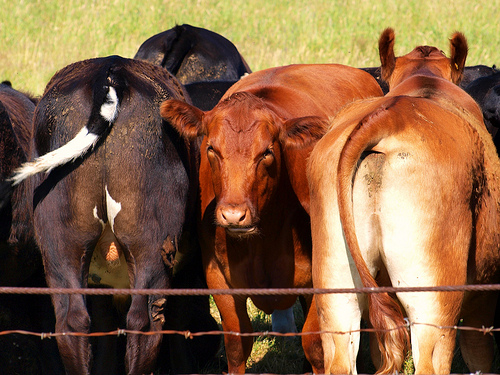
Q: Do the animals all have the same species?
A: Yes, all the animals are cows.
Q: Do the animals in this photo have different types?
A: No, all the animals are cows.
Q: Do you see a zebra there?
A: No, there are no zebras.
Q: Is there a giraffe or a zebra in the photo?
A: No, there are no zebras or giraffes.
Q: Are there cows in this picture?
A: Yes, there is a cow.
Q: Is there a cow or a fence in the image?
A: Yes, there is a cow.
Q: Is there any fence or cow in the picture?
A: Yes, there is a cow.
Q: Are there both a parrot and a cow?
A: No, there is a cow but no parrots.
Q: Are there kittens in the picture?
A: No, there are no kittens.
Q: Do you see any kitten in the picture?
A: No, there are no kittens.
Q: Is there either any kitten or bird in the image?
A: No, there are no kittens or birds.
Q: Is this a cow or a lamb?
A: This is a cow.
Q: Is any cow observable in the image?
A: Yes, there is a cow.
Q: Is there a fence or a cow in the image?
A: Yes, there is a cow.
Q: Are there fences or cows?
A: Yes, there is a cow.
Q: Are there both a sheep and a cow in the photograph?
A: No, there is a cow but no sheep.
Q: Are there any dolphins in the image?
A: No, there are no dolphins.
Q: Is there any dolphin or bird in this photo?
A: No, there are no dolphins or birds.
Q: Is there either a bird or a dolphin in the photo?
A: No, there are no dolphins or birds.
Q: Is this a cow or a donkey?
A: This is a cow.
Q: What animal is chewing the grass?
A: The animal is a cow.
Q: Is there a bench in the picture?
A: No, there are no benches.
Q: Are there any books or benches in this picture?
A: No, there are no benches or books.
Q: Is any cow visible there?
A: Yes, there is a cow.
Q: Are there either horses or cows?
A: Yes, there is a cow.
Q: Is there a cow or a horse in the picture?
A: Yes, there is a cow.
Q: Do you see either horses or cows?
A: Yes, there is a cow.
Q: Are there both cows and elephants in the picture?
A: No, there is a cow but no elephants.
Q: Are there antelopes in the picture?
A: No, there are no antelopes.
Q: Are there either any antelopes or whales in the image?
A: No, there are no antelopes or whales.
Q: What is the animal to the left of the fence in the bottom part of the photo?
A: The animal is a cow.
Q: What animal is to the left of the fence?
A: The animal is a cow.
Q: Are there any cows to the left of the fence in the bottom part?
A: Yes, there is a cow to the left of the fence.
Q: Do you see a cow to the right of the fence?
A: No, the cow is to the left of the fence.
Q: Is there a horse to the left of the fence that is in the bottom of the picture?
A: No, there is a cow to the left of the fence.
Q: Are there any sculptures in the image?
A: No, there are no sculptures.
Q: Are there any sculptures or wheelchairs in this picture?
A: No, there are no sculptures or wheelchairs.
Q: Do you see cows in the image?
A: Yes, there is a cow.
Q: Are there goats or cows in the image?
A: Yes, there is a cow.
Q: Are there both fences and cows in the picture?
A: Yes, there are both a cow and a fence.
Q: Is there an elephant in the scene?
A: No, there are no elephants.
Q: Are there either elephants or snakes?
A: No, there are no elephants or snakes.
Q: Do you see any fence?
A: Yes, there is a fence.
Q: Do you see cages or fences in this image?
A: Yes, there is a fence.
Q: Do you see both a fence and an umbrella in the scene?
A: No, there is a fence but no umbrellas.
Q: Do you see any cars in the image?
A: No, there are no cars.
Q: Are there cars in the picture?
A: No, there are no cars.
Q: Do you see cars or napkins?
A: No, there are no cars or napkins.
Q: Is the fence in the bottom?
A: Yes, the fence is in the bottom of the image.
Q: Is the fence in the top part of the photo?
A: No, the fence is in the bottom of the image.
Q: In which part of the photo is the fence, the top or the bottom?
A: The fence is in the bottom of the image.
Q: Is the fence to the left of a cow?
A: No, the fence is to the right of a cow.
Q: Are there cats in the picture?
A: No, there are no cats.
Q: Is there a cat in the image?
A: No, there are no cats.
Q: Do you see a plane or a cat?
A: No, there are no cats or airplanes.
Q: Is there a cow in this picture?
A: Yes, there are cows.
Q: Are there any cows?
A: Yes, there are cows.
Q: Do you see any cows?
A: Yes, there are cows.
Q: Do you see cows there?
A: Yes, there are cows.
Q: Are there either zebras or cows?
A: Yes, there are cows.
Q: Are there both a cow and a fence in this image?
A: Yes, there are both a cow and a fence.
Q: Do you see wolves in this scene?
A: No, there are no wolves.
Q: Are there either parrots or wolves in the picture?
A: No, there are no wolves or parrots.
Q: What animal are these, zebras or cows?
A: These are cows.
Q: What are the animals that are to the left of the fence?
A: The animals are cows.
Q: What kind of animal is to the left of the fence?
A: The animals are cows.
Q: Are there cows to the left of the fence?
A: Yes, there are cows to the left of the fence.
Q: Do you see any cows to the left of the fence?
A: Yes, there are cows to the left of the fence.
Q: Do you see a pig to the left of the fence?
A: No, there are cows to the left of the fence.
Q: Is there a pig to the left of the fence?
A: No, there are cows to the left of the fence.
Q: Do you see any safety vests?
A: No, there are no safety vests.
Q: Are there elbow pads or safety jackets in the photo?
A: No, there are no safety jackets or elbow pads.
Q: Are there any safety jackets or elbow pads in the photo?
A: No, there are no safety jackets or elbow pads.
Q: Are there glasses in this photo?
A: No, there are no glasses.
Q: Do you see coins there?
A: No, there are no coins.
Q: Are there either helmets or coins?
A: No, there are no coins or helmets.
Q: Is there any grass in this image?
A: Yes, there is grass.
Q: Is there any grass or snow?
A: Yes, there is grass.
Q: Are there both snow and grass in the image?
A: No, there is grass but no snow.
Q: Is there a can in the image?
A: No, there are no cans.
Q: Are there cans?
A: No, there are no cans.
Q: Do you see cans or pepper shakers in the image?
A: No, there are no cans or pepper shakers.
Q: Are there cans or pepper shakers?
A: No, there are no cans or pepper shakers.